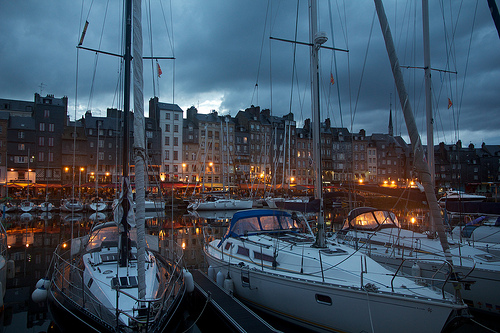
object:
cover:
[224, 209, 306, 238]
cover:
[340, 206, 402, 232]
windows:
[85, 225, 120, 250]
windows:
[221, 211, 309, 232]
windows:
[341, 218, 349, 230]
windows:
[164, 148, 169, 160]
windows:
[173, 149, 179, 159]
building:
[6, 90, 274, 200]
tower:
[388, 93, 394, 136]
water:
[9, 225, 37, 250]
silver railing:
[389, 251, 459, 303]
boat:
[200, 210, 463, 331]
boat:
[36, 199, 54, 211]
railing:
[131, 0, 147, 309]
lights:
[0, 160, 451, 253]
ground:
[364, 140, 423, 184]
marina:
[0, 305, 57, 333]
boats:
[334, 203, 500, 309]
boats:
[199, 0, 469, 333]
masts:
[308, 0, 333, 247]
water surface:
[8, 255, 41, 282]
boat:
[188, 195, 255, 210]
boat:
[438, 181, 485, 211]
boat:
[431, 210, 500, 245]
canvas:
[130, 4, 167, 302]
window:
[349, 210, 378, 232]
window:
[373, 210, 394, 228]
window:
[389, 210, 403, 228]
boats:
[20, 201, 34, 212]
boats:
[32, 0, 196, 332]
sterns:
[0, 201, 20, 214]